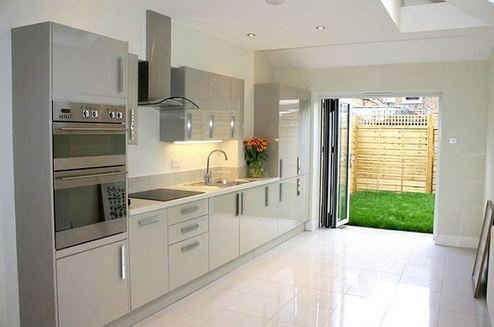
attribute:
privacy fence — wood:
[344, 110, 439, 203]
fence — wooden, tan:
[350, 116, 438, 195]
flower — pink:
[258, 145, 263, 151]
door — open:
[324, 95, 436, 236]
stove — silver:
[54, 163, 130, 248]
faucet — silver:
[203, 145, 231, 192]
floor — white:
[277, 242, 457, 294]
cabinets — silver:
[51, 27, 491, 321]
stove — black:
[132, 179, 208, 206]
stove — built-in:
[50, 97, 135, 244]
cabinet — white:
[208, 182, 264, 265]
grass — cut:
[354, 189, 418, 235]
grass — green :
[357, 190, 426, 225]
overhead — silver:
[141, 7, 176, 101]